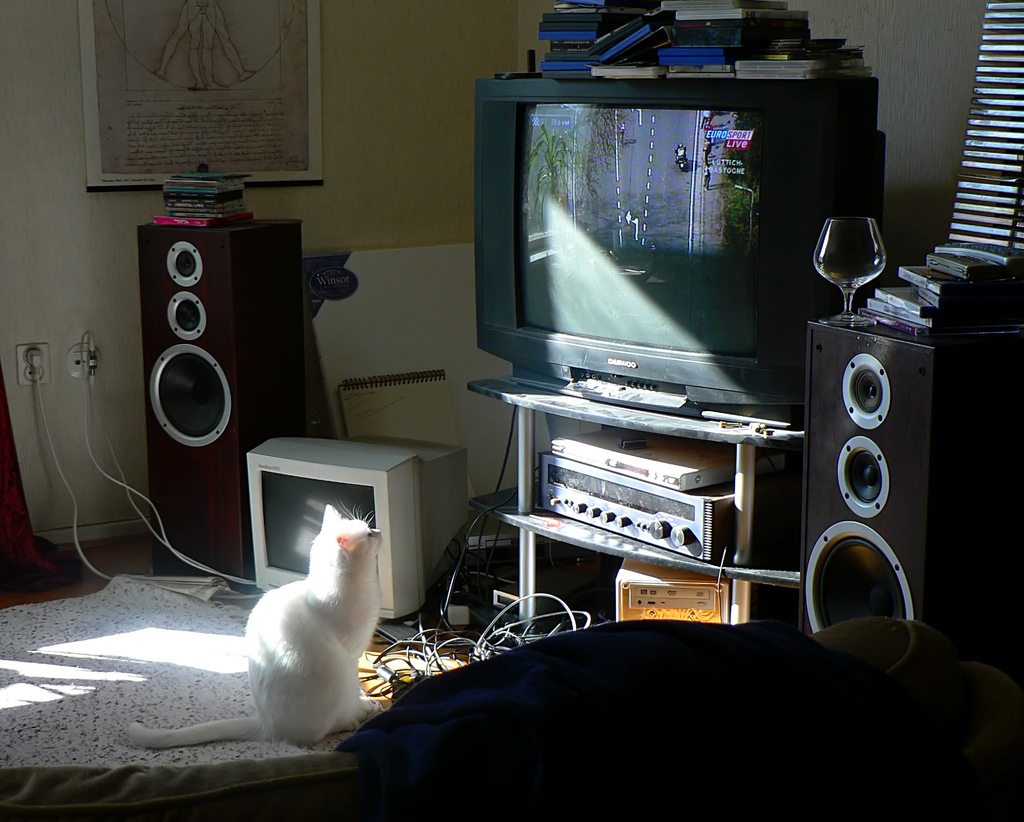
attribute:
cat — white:
[138, 494, 406, 760]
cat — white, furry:
[117, 484, 396, 759]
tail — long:
[114, 704, 262, 756]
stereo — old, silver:
[527, 429, 735, 577]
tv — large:
[456, 52, 891, 435]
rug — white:
[1, 575, 351, 768]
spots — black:
[1, 566, 267, 767]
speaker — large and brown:
[160, 269, 253, 568]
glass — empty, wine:
[822, 210, 918, 358]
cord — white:
[39, 378, 225, 593]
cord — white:
[501, 576, 597, 635]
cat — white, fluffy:
[106, 479, 381, 773]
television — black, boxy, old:
[449, 51, 910, 419]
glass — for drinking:
[799, 200, 899, 322]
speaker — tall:
[121, 192, 336, 582]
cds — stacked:
[925, 6, 1021, 270]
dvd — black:
[523, 430, 738, 575]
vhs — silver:
[523, 423, 735, 586]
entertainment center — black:
[516, 401, 832, 628]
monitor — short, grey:
[244, 430, 478, 627]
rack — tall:
[914, 2, 1018, 292]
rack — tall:
[925, 6, 1021, 300]